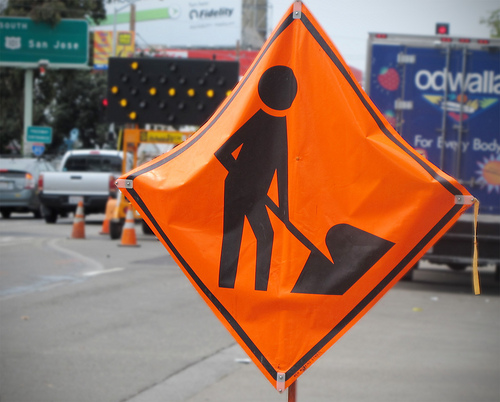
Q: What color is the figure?
A: Black.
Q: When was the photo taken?
A: Daytime.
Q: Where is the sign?
A: At a construction site.